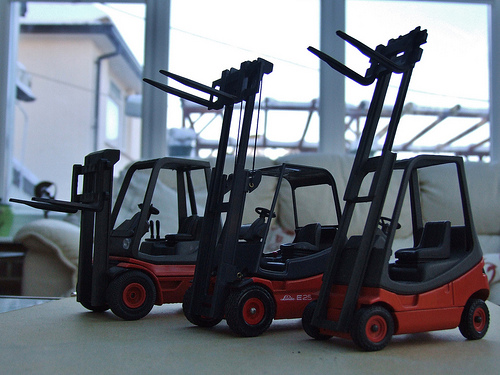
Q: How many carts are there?
A: 3.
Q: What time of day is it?
A: Afternoon.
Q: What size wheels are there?
A: Small.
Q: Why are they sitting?
A: Not in use.